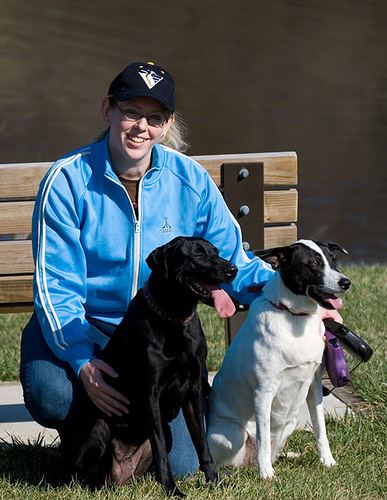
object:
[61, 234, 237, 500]
dog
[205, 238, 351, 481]
dog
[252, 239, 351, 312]
head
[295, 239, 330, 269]
streak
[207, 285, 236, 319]
tongue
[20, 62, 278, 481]
woman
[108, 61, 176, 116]
hat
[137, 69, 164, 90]
logo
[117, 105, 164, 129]
glasses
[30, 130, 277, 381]
jacket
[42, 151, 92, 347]
stripes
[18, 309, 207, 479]
jeans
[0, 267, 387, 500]
grass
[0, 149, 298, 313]
bench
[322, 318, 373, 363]
leads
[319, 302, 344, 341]
hand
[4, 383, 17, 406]
concrete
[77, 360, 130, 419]
right hand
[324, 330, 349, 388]
leash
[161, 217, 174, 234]
logo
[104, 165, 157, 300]
zipper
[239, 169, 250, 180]
bolt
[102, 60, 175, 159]
head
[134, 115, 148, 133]
nose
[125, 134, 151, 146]
mouth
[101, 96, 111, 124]
ear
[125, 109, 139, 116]
eye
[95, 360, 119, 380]
thumb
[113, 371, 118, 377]
thumbnail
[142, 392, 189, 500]
leg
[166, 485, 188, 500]
paw